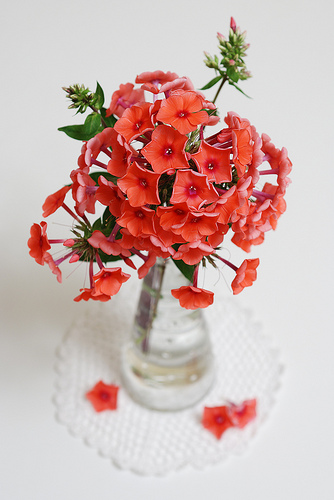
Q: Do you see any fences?
A: No, there are no fences.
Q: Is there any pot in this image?
A: No, there are no pots.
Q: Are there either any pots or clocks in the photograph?
A: No, there are no pots or clocks.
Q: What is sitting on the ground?
A: The flower is sitting on the ground.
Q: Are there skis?
A: No, there are no skis.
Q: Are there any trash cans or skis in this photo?
A: No, there are no skis or trash cans.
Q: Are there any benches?
A: No, there are no benches.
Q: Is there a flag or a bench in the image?
A: No, there are no benches or flags.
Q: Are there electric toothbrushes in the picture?
A: No, there are no electric toothbrushes.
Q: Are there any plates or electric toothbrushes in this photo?
A: No, there are no electric toothbrushes or plates.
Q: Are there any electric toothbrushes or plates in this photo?
A: No, there are no electric toothbrushes or plates.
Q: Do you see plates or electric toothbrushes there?
A: No, there are no electric toothbrushes or plates.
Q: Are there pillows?
A: No, there are no pillows.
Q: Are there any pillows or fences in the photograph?
A: No, there are no pillows or fences.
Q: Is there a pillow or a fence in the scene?
A: No, there are no pillows or fences.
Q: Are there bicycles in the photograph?
A: No, there are no bicycles.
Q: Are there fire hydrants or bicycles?
A: No, there are no bicycles or fire hydrants.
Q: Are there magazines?
A: No, there are no magazines.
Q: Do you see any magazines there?
A: No, there are no magazines.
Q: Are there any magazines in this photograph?
A: No, there are no magazines.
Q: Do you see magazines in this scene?
A: No, there are no magazines.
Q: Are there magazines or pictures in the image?
A: No, there are no magazines or pictures.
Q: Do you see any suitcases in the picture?
A: No, there are no suitcases.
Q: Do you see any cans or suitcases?
A: No, there are no suitcases or cans.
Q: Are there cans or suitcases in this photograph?
A: No, there are no suitcases or cans.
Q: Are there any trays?
A: No, there are no trays.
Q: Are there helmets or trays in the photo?
A: No, there are no trays or helmets.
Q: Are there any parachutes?
A: No, there are no parachutes.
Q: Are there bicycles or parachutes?
A: No, there are no parachutes or bicycles.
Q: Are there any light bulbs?
A: No, there are no light bulbs.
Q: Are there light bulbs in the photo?
A: No, there are no light bulbs.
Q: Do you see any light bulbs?
A: No, there are no light bulbs.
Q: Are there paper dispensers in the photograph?
A: No, there are no paper dispensers.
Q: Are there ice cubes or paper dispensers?
A: No, there are no paper dispensers or ice cubes.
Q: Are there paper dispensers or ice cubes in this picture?
A: No, there are no paper dispensers or ice cubes.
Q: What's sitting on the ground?
A: The flower is sitting on the ground.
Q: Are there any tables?
A: Yes, there is a table.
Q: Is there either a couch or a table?
A: Yes, there is a table.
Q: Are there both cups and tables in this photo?
A: No, there is a table but no cups.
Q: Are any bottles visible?
A: No, there are no bottles.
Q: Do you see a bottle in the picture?
A: No, there are no bottles.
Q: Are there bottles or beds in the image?
A: No, there are no bottles or beds.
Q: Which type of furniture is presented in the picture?
A: The furniture is a table.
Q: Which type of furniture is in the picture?
A: The furniture is a table.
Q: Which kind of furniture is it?
A: The piece of furniture is a table.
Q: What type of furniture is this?
A: This is a table.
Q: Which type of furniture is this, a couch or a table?
A: This is a table.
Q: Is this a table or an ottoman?
A: This is a table.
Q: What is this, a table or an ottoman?
A: This is a table.